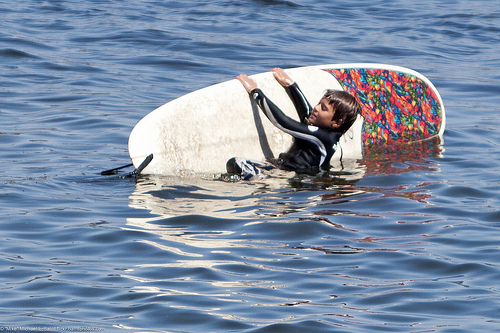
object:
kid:
[225, 67, 364, 178]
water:
[3, 2, 499, 332]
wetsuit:
[249, 129, 334, 181]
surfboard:
[127, 62, 448, 178]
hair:
[321, 89, 358, 130]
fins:
[103, 155, 169, 178]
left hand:
[234, 75, 260, 92]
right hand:
[271, 66, 302, 91]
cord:
[124, 162, 203, 178]